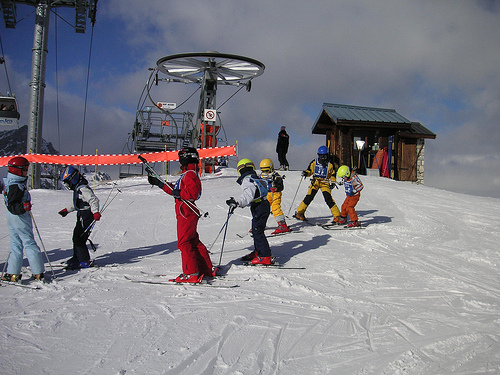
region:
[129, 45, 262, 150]
Ski lift at the top of the hill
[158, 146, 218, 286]
Woman in red getting ready to ski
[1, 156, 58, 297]
Child in blue getting ready to ski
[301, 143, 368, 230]
Group of kids preparing to ski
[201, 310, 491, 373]
Ski tracks in the snow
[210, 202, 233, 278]
Kid sized ski poles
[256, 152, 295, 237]
Kid with yellow helmet preparing to ski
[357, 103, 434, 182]
shack filled with ski equipment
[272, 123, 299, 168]
Skier dressed in all black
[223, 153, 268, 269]
Skier with bright yellow helmet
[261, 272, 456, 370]
the hill is covered in snow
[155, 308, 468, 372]
ski marks in the snow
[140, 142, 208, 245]
skier holding their ski poles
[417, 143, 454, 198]
building wall is made of stones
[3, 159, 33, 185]
the skier's helmet is red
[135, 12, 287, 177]
the ski lift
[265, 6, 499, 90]
big puffy clouds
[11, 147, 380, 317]
seven skiers in the group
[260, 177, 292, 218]
skier has a yellow ski suit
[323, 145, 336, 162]
skier's helmet is blue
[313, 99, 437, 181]
Small wooden house atop hill.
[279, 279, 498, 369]
Snow with ski tracks.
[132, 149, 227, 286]
Skier with red suit and carrying skies.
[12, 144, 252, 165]
Orange caution banner.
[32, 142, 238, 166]
Orange banner with red and white trimming.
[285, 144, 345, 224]
Skier in yellow suit having trouble.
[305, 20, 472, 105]
Blue sky with heavy clouds.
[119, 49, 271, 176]
Ski lift atop of hill.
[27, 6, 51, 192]
Tall metal cable pole.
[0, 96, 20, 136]
White ski lift.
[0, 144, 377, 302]
group of skiers standing around on the snow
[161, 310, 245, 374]
ski marks in the snow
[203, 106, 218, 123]
red, white, and black sign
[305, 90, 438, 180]
wooden shack with a blue shingled roof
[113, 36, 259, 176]
ski lift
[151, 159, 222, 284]
red snowsuit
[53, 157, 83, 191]
head angled down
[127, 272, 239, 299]
long and thin ski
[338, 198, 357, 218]
two knees turned inward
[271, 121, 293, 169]
person wearing all black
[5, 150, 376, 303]
children skiing in a line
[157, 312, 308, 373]
ski tracks in the snow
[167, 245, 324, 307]
red ski boots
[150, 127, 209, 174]
a black ski helmet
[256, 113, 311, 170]
an adult supervising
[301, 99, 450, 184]
A shed to hold ski equipment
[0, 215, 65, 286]
blue snow pants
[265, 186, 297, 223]
a pair of yellow snowpants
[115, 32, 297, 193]
a ski lift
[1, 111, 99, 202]
the top of a mountain